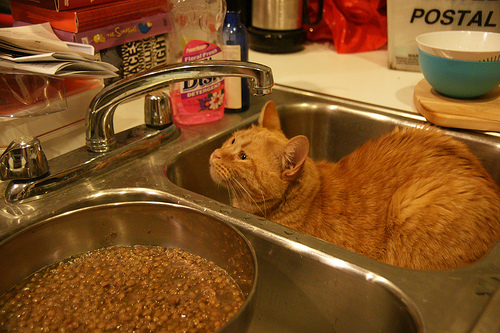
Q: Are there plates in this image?
A: Yes, there is a plate.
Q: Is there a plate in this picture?
A: Yes, there is a plate.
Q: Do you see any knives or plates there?
A: Yes, there is a plate.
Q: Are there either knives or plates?
A: Yes, there is a plate.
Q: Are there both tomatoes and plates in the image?
A: No, there is a plate but no tomatoes.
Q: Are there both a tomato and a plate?
A: No, there is a plate but no tomatoes.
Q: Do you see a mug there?
A: No, there are no mugs.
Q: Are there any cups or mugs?
A: No, there are no mugs or cups.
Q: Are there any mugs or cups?
A: No, there are no mugs or cups.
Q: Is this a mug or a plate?
A: This is a plate.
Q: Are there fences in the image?
A: No, there are no fences.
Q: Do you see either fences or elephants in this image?
A: No, there are no fences or elephants.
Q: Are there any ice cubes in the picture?
A: No, there are no ice cubes.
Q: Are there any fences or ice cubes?
A: No, there are no ice cubes or fences.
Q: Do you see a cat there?
A: Yes, there is a cat.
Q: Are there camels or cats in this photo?
A: Yes, there is a cat.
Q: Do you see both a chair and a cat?
A: No, there is a cat but no chairs.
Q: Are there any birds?
A: No, there are no birds.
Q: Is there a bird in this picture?
A: No, there are no birds.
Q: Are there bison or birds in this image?
A: No, there are no birds or bison.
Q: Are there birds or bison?
A: No, there are no birds or bison.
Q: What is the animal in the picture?
A: The animal is a cat.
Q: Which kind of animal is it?
A: The animal is a cat.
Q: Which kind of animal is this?
A: This is a cat.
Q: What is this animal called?
A: This is a cat.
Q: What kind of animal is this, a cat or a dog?
A: This is a cat.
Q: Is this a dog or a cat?
A: This is a cat.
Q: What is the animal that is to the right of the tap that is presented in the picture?
A: The animal is a cat.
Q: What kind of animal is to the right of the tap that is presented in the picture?
A: The animal is a cat.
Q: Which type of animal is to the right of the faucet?
A: The animal is a cat.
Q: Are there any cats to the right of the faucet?
A: Yes, there is a cat to the right of the faucet.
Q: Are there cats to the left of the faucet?
A: No, the cat is to the right of the faucet.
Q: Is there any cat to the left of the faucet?
A: No, the cat is to the right of the faucet.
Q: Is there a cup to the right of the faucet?
A: No, there is a cat to the right of the faucet.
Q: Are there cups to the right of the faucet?
A: No, there is a cat to the right of the faucet.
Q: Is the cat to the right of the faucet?
A: Yes, the cat is to the right of the faucet.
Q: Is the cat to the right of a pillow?
A: No, the cat is to the right of the faucet.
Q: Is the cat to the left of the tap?
A: No, the cat is to the right of the tap.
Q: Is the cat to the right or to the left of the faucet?
A: The cat is to the right of the faucet.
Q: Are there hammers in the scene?
A: No, there are no hammers.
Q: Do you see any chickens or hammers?
A: No, there are no hammers or chickens.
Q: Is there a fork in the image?
A: No, there are no forks.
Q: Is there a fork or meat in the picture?
A: No, there are no forks or meat.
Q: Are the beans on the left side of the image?
A: Yes, the beans are on the left of the image.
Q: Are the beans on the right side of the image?
A: No, the beans are on the left of the image.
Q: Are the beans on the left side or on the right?
A: The beans are on the left of the image.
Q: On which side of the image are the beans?
A: The beans are on the left of the image.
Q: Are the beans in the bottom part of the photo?
A: Yes, the beans are in the bottom of the image.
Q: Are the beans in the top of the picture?
A: No, the beans are in the bottom of the image.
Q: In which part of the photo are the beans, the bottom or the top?
A: The beans are in the bottom of the image.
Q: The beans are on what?
A: The beans are on the plate.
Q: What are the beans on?
A: The beans are on the plate.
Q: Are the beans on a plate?
A: Yes, the beans are on a plate.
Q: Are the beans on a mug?
A: No, the beans are on a plate.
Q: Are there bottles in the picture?
A: Yes, there is a bottle.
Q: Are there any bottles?
A: Yes, there is a bottle.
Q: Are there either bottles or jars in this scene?
A: Yes, there is a bottle.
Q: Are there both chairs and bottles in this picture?
A: No, there is a bottle but no chairs.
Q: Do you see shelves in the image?
A: No, there are no shelves.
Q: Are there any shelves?
A: No, there are no shelves.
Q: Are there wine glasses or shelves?
A: No, there are no shelves or wine glasses.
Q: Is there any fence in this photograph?
A: No, there are no fences.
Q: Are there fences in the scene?
A: No, there are no fences.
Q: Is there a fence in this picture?
A: No, there are no fences.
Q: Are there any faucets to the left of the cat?
A: Yes, there is a faucet to the left of the cat.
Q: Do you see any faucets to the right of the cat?
A: No, the faucet is to the left of the cat.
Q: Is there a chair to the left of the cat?
A: No, there is a faucet to the left of the cat.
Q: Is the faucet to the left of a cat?
A: Yes, the faucet is to the left of a cat.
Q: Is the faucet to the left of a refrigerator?
A: No, the faucet is to the left of a cat.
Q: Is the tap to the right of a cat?
A: No, the tap is to the left of a cat.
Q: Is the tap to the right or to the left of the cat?
A: The tap is to the left of the cat.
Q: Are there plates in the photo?
A: Yes, there is a plate.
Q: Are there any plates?
A: Yes, there is a plate.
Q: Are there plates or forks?
A: Yes, there is a plate.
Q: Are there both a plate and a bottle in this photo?
A: Yes, there are both a plate and a bottle.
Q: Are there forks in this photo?
A: No, there are no forks.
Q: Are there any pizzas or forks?
A: No, there are no forks or pizzas.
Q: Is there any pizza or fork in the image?
A: No, there are no forks or pizzas.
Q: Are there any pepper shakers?
A: No, there are no pepper shakers.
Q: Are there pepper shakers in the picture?
A: No, there are no pepper shakers.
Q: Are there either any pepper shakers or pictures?
A: No, there are no pepper shakers or pictures.